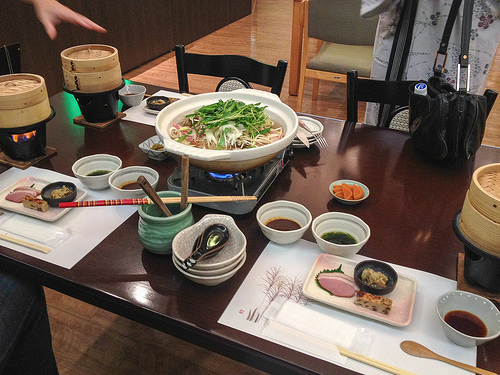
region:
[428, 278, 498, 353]
a white bowl on table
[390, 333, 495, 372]
a brown wood spoon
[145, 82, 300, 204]
a pot on a burner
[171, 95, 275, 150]
green vegetables in a pot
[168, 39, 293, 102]
a chair in front a table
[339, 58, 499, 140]
a chair in front a table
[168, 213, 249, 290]
white bowls on table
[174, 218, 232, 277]
a spoon on white dish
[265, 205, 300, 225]
A bowl with sauce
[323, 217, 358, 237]
A bowl with green sauce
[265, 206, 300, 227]
A bowl with red sauce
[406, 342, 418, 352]
A wooden spoon on a mat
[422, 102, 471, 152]
A bag on the table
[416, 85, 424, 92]
A bottle top sticking out of the bag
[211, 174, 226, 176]
A blue flame cooking food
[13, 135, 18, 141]
A flame from a stove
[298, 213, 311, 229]
a white bowl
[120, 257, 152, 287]
a shadow on the table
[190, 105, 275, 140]
food in the bowl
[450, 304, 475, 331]
brown soup in the bowl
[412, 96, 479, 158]
a purse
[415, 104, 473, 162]
the purse is black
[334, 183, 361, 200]
oranges in a bowl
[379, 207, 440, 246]
a brown table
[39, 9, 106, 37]
a persons hand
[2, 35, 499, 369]
the table is ready for diners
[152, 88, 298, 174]
a wok is in the middle of the table setting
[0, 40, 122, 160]
wooden bamboo boxes are on the table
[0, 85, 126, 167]
portable flame heaters are under the boxes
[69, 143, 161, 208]
two dishes are at each setting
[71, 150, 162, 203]
the dishes have dipping sauces in them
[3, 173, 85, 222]
a rectangular plate has items to eat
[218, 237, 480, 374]
the dishes are on a white placemat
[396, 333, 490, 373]
a wooden spoon is on the mat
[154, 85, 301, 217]
the bowl with food has a portable stove underneath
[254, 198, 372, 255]
two little white food bowls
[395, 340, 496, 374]
one long handled wooden spoon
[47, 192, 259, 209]
long wooden chopsticks resting on bowl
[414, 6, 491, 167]
one long handled black purse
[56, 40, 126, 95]
little round light colored bamboo container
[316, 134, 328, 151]
shiny metal fork tines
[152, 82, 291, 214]
large white dish on hot plate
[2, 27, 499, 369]
one dark wooden table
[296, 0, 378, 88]
back of green cushioned chair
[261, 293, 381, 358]
white napkin wrapped in plastic